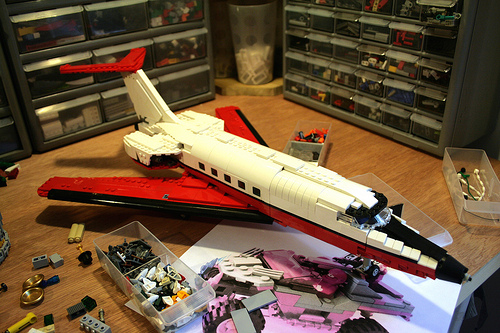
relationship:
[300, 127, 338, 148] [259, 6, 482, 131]
lego in shelve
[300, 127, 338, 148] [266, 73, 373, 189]
lego in container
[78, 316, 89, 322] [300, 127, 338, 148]
hole in lego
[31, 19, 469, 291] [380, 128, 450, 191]
plane on desk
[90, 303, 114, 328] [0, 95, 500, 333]
brick on desk